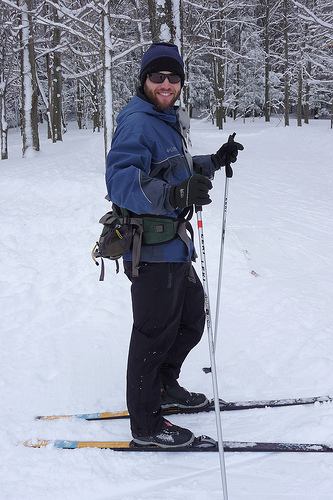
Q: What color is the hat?
A: Blue and black.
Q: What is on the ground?
A: Snow.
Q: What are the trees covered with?
A: Snow.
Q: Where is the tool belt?
A: Around waist.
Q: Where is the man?
A: Standing in the snow.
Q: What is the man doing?
A: Cross country skiing.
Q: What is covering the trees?
A: Snow.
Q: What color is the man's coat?
A: Blue.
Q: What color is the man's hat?
A: Blue.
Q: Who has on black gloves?
A: The skier.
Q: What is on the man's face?
A: Sunglasses.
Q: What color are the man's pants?
A: Black.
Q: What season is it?
A: Winter.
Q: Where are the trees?
A: Behind the man.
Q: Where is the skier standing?
A: On flat snow.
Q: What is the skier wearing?
A: A blue and black knit hat.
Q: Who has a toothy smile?
A: The bearded skier.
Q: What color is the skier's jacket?
A: Grey and blue.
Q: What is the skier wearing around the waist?
A: A waistpack with many straps.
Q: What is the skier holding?
A: Silver poles with writing.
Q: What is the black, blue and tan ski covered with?
A: Snow.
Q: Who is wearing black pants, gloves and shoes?
A: The skier.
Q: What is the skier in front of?
A: Trees covered in snow.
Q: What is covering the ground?
A: Snow.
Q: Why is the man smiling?
A: Taking a picture.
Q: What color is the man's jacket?
A: Blue.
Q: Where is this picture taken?
A: Mountain.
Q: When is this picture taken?
A: While skiing.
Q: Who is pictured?
A: A man skier.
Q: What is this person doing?
A: Skiing.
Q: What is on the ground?
A: Snow.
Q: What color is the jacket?
A: Blue.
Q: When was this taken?
A: Winter.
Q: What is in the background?
A: Trees.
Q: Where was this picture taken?
A: Slopes.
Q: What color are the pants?
A: Black.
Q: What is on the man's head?
A: Hat.